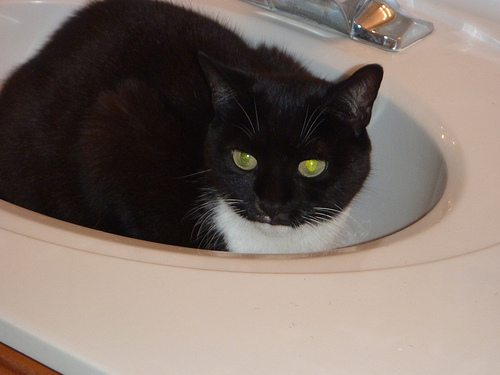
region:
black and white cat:
[5, 2, 382, 258]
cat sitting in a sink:
[5, 1, 480, 358]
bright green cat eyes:
[226, 147, 328, 179]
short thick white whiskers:
[187, 187, 370, 254]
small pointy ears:
[191, 45, 382, 123]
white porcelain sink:
[10, 2, 482, 347]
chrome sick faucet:
[273, 0, 445, 64]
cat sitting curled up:
[6, 5, 382, 264]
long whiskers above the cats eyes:
[236, 98, 326, 144]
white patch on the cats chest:
[209, 190, 350, 253]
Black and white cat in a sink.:
[8, 2, 408, 268]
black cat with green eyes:
[3, 46, 378, 251]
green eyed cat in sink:
[168, 57, 395, 254]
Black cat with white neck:
[198, 55, 390, 267]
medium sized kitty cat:
[157, 32, 424, 279]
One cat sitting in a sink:
[1, 5, 398, 272]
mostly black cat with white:
[1, 50, 391, 258]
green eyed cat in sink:
[1, 2, 392, 279]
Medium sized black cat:
[0, 0, 400, 291]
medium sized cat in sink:
[35, 22, 393, 280]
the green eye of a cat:
[232, 148, 256, 172]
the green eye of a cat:
[295, 158, 327, 177]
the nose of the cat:
[257, 193, 282, 212]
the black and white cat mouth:
[252, 212, 292, 235]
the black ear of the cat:
[195, 51, 250, 101]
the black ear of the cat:
[340, 61, 387, 120]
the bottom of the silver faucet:
[251, 1, 433, 52]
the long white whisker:
[187, 198, 243, 210]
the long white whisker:
[311, 205, 363, 233]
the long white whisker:
[297, 213, 347, 243]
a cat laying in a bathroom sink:
[1, 4, 455, 262]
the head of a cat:
[199, 46, 389, 233]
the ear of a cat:
[196, 51, 251, 119]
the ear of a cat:
[321, 59, 386, 133]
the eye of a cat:
[224, 140, 265, 176]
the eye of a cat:
[293, 149, 335, 184]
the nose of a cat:
[250, 177, 294, 220]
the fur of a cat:
[74, 62, 146, 137]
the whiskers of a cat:
[181, 188, 251, 252]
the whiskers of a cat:
[294, 195, 369, 250]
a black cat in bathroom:
[3, 3, 382, 249]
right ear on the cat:
[188, 49, 236, 108]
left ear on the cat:
[339, 64, 394, 116]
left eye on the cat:
[296, 153, 331, 182]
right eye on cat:
[227, 141, 257, 174]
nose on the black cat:
[255, 185, 292, 214]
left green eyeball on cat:
[306, 158, 324, 175]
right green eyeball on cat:
[239, 151, 254, 166]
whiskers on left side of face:
[299, 204, 356, 251]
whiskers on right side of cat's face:
[185, 188, 243, 245]